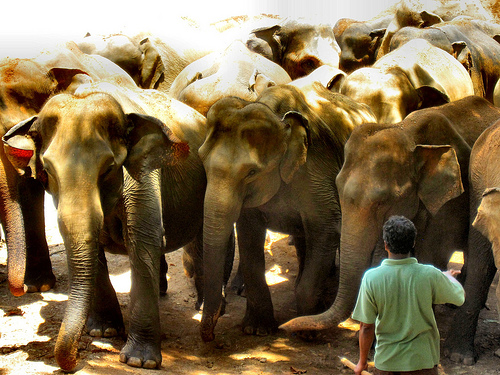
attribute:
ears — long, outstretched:
[107, 111, 202, 188]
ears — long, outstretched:
[0, 102, 43, 184]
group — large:
[8, 1, 485, 337]